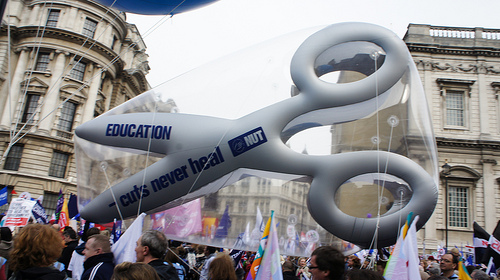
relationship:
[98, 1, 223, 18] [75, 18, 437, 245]
balloon above scissors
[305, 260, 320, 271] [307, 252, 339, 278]
shades in face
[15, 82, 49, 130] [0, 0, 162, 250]
window on building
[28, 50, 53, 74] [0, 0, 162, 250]
window on building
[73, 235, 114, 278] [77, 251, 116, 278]
man wearing jacket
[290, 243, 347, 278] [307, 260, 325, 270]
man wearing sunglasses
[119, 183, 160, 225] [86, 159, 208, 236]
cuts on blade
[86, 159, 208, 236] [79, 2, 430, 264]
blade of scissor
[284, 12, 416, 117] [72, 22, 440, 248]
handle of inflatable scissors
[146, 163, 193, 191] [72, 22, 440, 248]
word on blade of inflatable scissors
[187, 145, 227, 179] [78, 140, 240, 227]
word on blade of scissors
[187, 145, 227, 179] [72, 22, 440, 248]
word on blade of inflatable scissors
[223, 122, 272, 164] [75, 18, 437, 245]
logo on scissors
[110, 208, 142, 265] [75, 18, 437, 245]
flag in front of scissors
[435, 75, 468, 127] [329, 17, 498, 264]
window on building